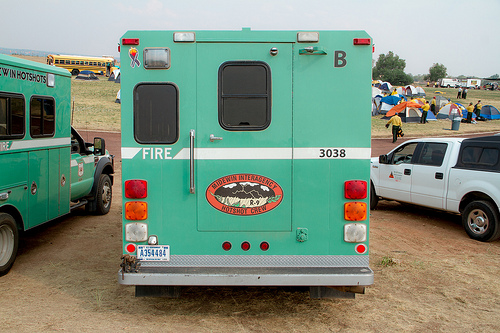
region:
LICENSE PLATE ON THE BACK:
[137, 245, 172, 263]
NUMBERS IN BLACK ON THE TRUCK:
[318, 148, 348, 158]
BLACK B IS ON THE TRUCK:
[330, 49, 349, 69]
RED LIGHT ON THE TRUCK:
[342, 184, 372, 199]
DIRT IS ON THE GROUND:
[433, 238, 448, 274]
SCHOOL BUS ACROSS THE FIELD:
[72, 55, 99, 65]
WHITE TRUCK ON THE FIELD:
[425, 189, 462, 193]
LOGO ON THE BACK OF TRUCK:
[206, 172, 286, 213]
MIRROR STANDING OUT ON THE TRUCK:
[90, 136, 104, 152]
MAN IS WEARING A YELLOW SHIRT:
[392, 119, 403, 126]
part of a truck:
[316, 213, 334, 235]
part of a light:
[353, 223, 363, 246]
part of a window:
[238, 95, 245, 112]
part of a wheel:
[12, 243, 24, 260]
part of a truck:
[145, 206, 159, 235]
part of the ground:
[402, 265, 422, 297]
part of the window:
[423, 156, 433, 170]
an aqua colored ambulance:
[113, 26, 374, 302]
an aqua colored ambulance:
[0, 50, 113, 279]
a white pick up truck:
[372, 128, 498, 240]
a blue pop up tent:
[480, 102, 497, 119]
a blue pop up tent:
[381, 94, 399, 103]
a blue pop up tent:
[419, 110, 433, 121]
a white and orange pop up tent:
[436, 102, 463, 119]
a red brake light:
[123, 179, 146, 199]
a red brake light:
[343, 179, 368, 200]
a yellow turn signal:
[343, 202, 368, 222]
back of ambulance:
[121, 28, 386, 282]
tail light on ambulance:
[341, 176, 372, 198]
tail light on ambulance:
[124, 180, 147, 198]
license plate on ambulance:
[140, 244, 170, 258]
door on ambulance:
[191, 39, 295, 230]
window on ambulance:
[135, 82, 181, 144]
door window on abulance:
[216, 61, 271, 126]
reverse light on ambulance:
[346, 220, 366, 245]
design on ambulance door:
[203, 175, 284, 215]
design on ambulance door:
[127, 48, 139, 66]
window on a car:
[205, 55, 280, 142]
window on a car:
[122, 80, 185, 159]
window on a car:
[411, 136, 453, 172]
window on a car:
[23, 93, 59, 142]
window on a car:
[0, 89, 34, 137]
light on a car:
[342, 178, 368, 205]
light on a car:
[338, 199, 370, 222]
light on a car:
[340, 220, 368, 243]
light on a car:
[352, 242, 369, 256]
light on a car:
[122, 220, 154, 242]